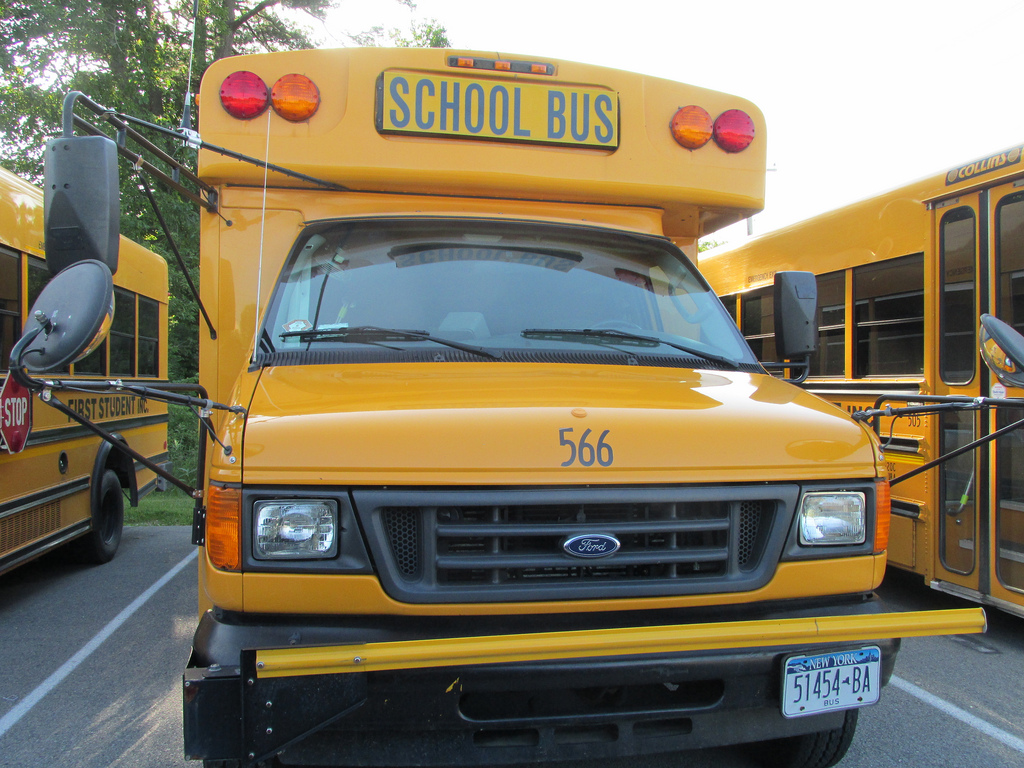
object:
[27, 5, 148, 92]
green leaves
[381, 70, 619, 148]
sign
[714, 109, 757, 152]
light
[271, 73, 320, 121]
light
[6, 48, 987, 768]
bus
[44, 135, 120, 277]
mirror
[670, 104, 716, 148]
light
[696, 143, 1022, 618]
bus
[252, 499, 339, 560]
headlight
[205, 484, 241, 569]
light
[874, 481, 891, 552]
light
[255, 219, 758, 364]
windshield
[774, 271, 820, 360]
mirror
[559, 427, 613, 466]
number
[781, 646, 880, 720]
license plate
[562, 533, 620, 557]
ford symbol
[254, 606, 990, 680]
crossing arm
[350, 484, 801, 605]
grill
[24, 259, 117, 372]
mirror